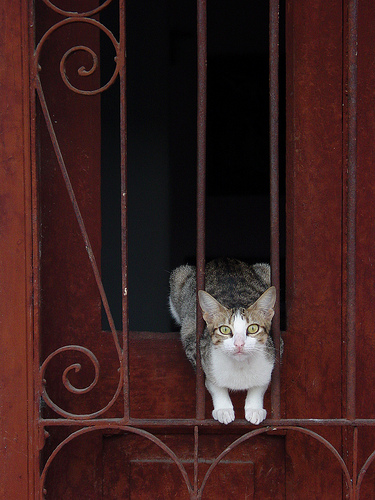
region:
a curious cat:
[179, 245, 281, 430]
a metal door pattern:
[28, 1, 133, 433]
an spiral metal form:
[22, 15, 125, 100]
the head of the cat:
[193, 292, 279, 364]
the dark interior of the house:
[98, 5, 285, 241]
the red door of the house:
[0, 1, 369, 260]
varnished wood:
[286, 11, 338, 305]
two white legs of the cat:
[206, 371, 279, 423]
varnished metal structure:
[26, 6, 353, 253]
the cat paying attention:
[165, 259, 273, 442]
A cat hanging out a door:
[152, 232, 304, 457]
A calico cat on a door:
[156, 230, 281, 438]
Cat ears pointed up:
[192, 289, 278, 320]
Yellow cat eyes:
[213, 319, 267, 339]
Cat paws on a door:
[199, 387, 281, 430]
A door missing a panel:
[84, 7, 311, 353]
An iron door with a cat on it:
[17, 24, 373, 497]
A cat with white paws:
[200, 369, 284, 431]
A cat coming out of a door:
[158, 248, 306, 431]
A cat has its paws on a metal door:
[162, 233, 299, 424]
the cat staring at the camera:
[166, 258, 282, 423]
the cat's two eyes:
[218, 320, 260, 335]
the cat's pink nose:
[234, 338, 244, 347]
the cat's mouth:
[232, 346, 245, 355]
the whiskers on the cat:
[211, 341, 277, 366]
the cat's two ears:
[195, 286, 275, 314]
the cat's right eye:
[217, 323, 233, 336]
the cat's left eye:
[245, 322, 259, 334]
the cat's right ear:
[196, 288, 223, 320]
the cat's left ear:
[246, 284, 277, 315]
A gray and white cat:
[161, 252, 305, 407]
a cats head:
[204, 285, 279, 361]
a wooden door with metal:
[13, 153, 352, 465]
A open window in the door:
[99, 23, 288, 253]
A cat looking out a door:
[156, 233, 324, 426]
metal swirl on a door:
[8, 326, 133, 416]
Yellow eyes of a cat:
[204, 320, 268, 341]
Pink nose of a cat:
[226, 340, 254, 356]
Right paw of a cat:
[192, 401, 238, 426]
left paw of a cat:
[241, 408, 273, 428]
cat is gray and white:
[115, 223, 323, 497]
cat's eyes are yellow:
[205, 314, 282, 350]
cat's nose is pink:
[223, 332, 255, 356]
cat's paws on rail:
[193, 391, 281, 439]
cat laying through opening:
[166, 218, 316, 412]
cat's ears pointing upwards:
[166, 252, 278, 316]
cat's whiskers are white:
[193, 320, 290, 369]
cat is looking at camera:
[182, 292, 292, 355]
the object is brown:
[35, 3, 371, 491]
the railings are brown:
[32, 33, 362, 452]